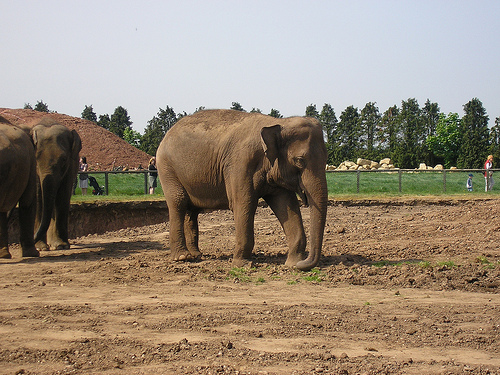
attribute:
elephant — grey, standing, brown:
[154, 109, 326, 268]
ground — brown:
[0, 170, 499, 374]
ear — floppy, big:
[260, 122, 281, 165]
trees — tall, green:
[15, 97, 498, 172]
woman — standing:
[148, 157, 158, 194]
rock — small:
[224, 340, 235, 349]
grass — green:
[72, 170, 498, 193]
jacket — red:
[482, 161, 494, 178]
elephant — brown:
[26, 120, 83, 252]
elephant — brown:
[1, 116, 42, 256]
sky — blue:
[0, 2, 499, 147]